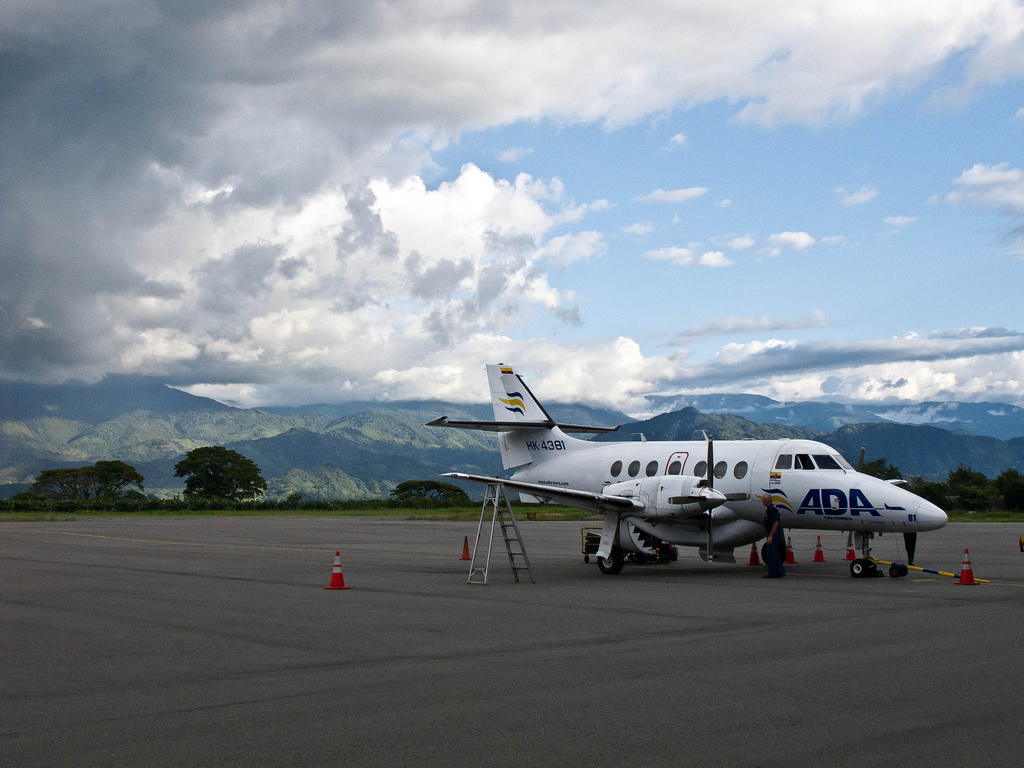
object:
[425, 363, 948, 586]
plane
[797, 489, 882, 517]
letters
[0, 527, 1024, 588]
stripes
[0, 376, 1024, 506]
mountain range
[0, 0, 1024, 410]
cloud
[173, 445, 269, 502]
trees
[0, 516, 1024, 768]
pavement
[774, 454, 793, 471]
cockpit windows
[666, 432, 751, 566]
propeller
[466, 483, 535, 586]
ladder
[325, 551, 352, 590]
cone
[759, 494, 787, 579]
person